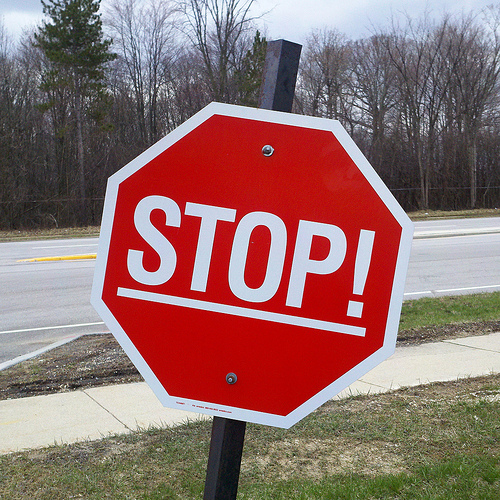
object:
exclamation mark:
[347, 229, 378, 320]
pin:
[226, 374, 237, 385]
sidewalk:
[2, 331, 500, 454]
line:
[19, 225, 498, 265]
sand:
[248, 434, 407, 485]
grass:
[2, 290, 498, 499]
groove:
[78, 388, 134, 432]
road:
[1, 217, 500, 375]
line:
[115, 288, 366, 337]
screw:
[263, 146, 275, 156]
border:
[89, 101, 414, 429]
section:
[344, 342, 499, 391]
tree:
[34, 1, 105, 214]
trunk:
[68, 82, 90, 202]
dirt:
[3, 331, 145, 400]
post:
[258, 39, 303, 112]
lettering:
[128, 194, 347, 309]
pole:
[205, 416, 247, 498]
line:
[0, 284, 499, 335]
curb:
[3, 331, 111, 379]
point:
[76, 327, 90, 346]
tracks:
[0, 370, 141, 398]